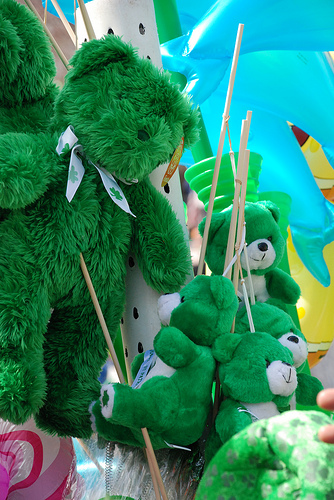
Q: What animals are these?
A: Bears.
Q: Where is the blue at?
A: Above the animals.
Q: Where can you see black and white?
A: Pole near bears.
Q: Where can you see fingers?
A: Bottom right.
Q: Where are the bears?
A: On sticks.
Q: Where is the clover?
A: Bear's white foot.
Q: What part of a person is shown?
A: Fingertips.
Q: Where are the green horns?
A: Behind bears.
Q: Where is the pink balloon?
A: Below large green bear.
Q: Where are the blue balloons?
A: Behind bears.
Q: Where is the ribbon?
A: Large bear's neck.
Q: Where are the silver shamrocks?
A: On green balloon.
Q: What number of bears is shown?
A: Six.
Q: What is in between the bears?
A: Sticks.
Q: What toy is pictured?
A: Stuffed animals.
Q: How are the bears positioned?
A: In a group.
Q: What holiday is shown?
A: St Patrick's day.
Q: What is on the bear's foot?
A: A green clover.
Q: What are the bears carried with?
A: Pole.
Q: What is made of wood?
A: Sticks.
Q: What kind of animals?
A: Plush.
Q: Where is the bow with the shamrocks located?
A: Bear.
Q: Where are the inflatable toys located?
A: Background.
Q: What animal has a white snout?
A: Bear.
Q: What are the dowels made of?
A: Wood.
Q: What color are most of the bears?
A: Green.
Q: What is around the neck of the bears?
A: A bow tie.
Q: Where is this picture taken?
A: A stuffed animal store.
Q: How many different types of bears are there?
A: Two.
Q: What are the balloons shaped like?
A: Dolphins.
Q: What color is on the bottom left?
A: Pink.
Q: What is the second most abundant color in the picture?
A: Blue.